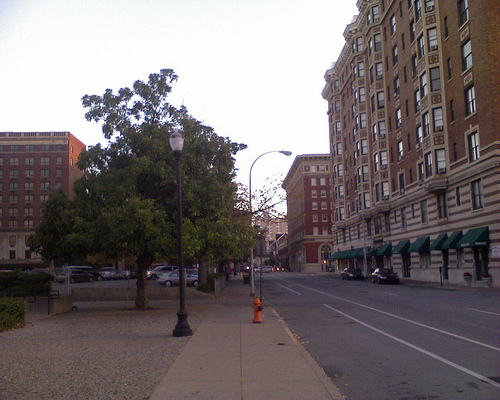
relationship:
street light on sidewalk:
[247, 149, 293, 299] [152, 271, 340, 398]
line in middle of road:
[297, 291, 454, 398] [270, 259, 496, 398]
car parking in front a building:
[339, 266, 364, 281] [321, 0, 498, 291]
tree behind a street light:
[26, 70, 252, 310] [169, 132, 194, 337]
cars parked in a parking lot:
[38, 259, 205, 286] [57, 269, 201, 302]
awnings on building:
[416, 225, 486, 259] [320, 205, 498, 269]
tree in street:
[26, 70, 252, 310] [261, 264, 493, 398]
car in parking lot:
[158, 270, 199, 287] [2, 267, 257, 373]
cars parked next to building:
[375, 270, 397, 287] [325, 77, 486, 280]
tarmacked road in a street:
[322, 283, 389, 355] [258, 235, 470, 395]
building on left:
[0, 132, 89, 283] [318, 205, 496, 325]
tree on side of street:
[26, 70, 252, 310] [77, 261, 195, 400]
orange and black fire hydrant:
[213, 296, 286, 347] [249, 294, 267, 324]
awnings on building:
[416, 225, 486, 259] [38, 134, 72, 288]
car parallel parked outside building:
[371, 268, 396, 281] [321, 0, 498, 291]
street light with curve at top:
[247, 149, 293, 299] [242, 113, 313, 246]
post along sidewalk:
[151, 116, 190, 347] [182, 262, 324, 398]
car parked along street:
[371, 268, 396, 281] [254, 271, 499, 397]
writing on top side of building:
[0, 130, 72, 139] [0, 132, 89, 283]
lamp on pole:
[168, 127, 193, 334] [168, 151, 190, 336]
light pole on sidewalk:
[164, 122, 205, 334] [200, 286, 250, 396]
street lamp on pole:
[260, 151, 292, 297] [240, 166, 258, 304]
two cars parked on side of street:
[338, 260, 403, 291] [261, 264, 493, 398]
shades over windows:
[329, 224, 487, 267] [388, 255, 489, 275]